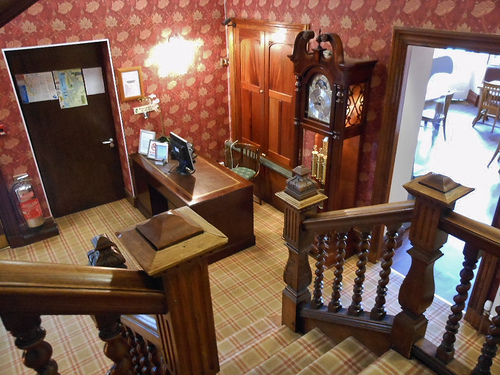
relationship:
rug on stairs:
[0, 193, 498, 372] [220, 319, 440, 374]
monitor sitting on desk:
[168, 131, 193, 177] [126, 145, 257, 261]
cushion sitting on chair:
[227, 165, 257, 183] [225, 139, 267, 209]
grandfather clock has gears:
[286, 31, 379, 267] [308, 144, 326, 189]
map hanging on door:
[52, 66, 91, 113] [2, 44, 124, 221]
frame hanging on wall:
[115, 65, 144, 104] [223, 0, 499, 238]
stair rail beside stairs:
[275, 169, 473, 373] [220, 319, 440, 374]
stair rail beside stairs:
[1, 207, 232, 374] [220, 319, 440, 374]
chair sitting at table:
[476, 84, 499, 136] [485, 80, 497, 89]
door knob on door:
[99, 137, 117, 151] [2, 44, 124, 221]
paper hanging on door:
[81, 67, 107, 95] [2, 44, 124, 221]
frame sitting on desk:
[152, 142, 168, 165] [126, 145, 257, 261]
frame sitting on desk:
[147, 139, 160, 160] [126, 145, 257, 261]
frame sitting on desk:
[137, 127, 155, 157] [126, 145, 257, 261]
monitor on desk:
[168, 131, 193, 177] [126, 145, 257, 261]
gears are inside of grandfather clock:
[308, 144, 326, 189] [286, 31, 379, 267]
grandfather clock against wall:
[286, 31, 379, 267] [223, 0, 499, 238]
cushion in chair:
[227, 165, 257, 183] [225, 139, 267, 209]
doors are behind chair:
[225, 18, 307, 211] [225, 139, 267, 209]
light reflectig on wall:
[145, 36, 207, 77] [223, 0, 499, 238]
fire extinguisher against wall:
[11, 179, 46, 229] [223, 0, 499, 238]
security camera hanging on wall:
[220, 14, 236, 32] [223, 0, 499, 238]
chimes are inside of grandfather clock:
[308, 144, 326, 189] [286, 31, 379, 267]